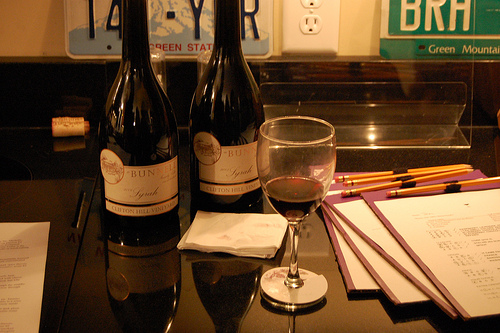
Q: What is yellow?
A: Pencils.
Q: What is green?
A: License plate.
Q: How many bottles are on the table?
A: Two.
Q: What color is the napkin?
A: White.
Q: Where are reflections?
A: On the table.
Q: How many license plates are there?
A: Two.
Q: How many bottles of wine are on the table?
A: Two.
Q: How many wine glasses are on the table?
A: One.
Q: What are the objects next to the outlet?
A: License plates.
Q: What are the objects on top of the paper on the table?
A: Pencils.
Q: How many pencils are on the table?
A: Four.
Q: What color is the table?
A: Black.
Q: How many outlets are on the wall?
A: One.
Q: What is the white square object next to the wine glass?
A: Napkin.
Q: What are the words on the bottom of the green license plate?
A: Green mountain.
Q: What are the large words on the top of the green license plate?
A: Bra.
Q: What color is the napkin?
A: White.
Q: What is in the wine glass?
A: Red Wine.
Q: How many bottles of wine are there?
A: Two.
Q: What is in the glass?
A: Wine.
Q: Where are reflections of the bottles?
A: On the table.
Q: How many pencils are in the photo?
A: Four.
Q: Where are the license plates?
A: Against the wall.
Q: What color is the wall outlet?
A: White.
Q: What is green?
A: A license plate.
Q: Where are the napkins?
A: Next to the bottles.